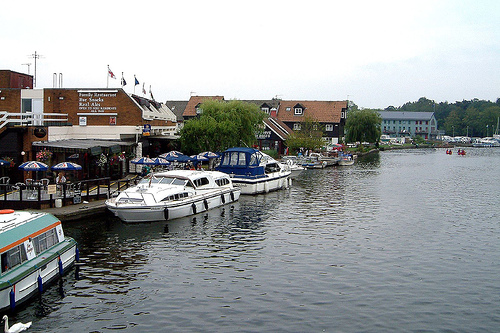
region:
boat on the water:
[100, 154, 265, 242]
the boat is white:
[106, 133, 263, 272]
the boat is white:
[114, 155, 214, 223]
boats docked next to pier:
[2, 121, 358, 330]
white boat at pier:
[90, 159, 260, 247]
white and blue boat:
[206, 138, 291, 207]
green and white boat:
[0, 204, 91, 319]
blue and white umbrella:
[21, 148, 86, 181]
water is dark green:
[268, 196, 463, 306]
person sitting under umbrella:
[46, 155, 83, 199]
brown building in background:
[2, 68, 197, 175]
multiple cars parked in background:
[367, 113, 499, 154]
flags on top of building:
[90, 63, 172, 120]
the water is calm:
[273, 196, 372, 271]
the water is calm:
[270, 220, 385, 300]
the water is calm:
[293, 229, 412, 327]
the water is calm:
[310, 220, 414, 291]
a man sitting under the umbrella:
[38, 153, 90, 211]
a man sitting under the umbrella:
[50, 152, 78, 204]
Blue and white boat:
[215, 140, 296, 200]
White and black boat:
[104, 157, 244, 224]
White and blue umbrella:
[17, 155, 49, 175]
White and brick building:
[0, 70, 175, 175]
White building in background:
[360, 109, 438, 141]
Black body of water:
[7, 145, 490, 330]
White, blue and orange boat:
[0, 202, 85, 312]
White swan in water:
[1, 313, 41, 330]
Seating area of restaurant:
[1, 172, 69, 208]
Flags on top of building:
[100, 62, 153, 99]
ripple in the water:
[288, 220, 318, 237]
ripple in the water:
[248, 281, 282, 303]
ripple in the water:
[355, 288, 387, 305]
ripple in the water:
[143, 291, 178, 312]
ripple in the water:
[442, 233, 463, 252]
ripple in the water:
[373, 243, 400, 265]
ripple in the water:
[331, 198, 365, 218]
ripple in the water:
[432, 176, 460, 195]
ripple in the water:
[346, 250, 384, 280]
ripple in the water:
[358, 190, 383, 208]